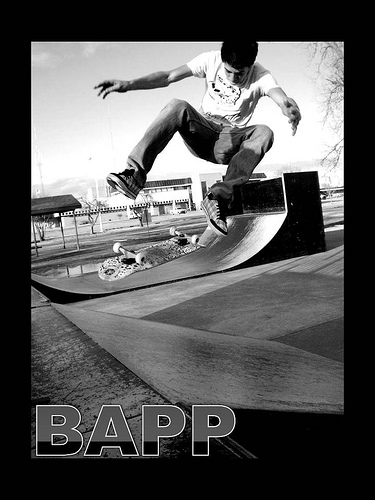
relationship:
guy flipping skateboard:
[92, 40, 301, 237] [97, 224, 201, 283]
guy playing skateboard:
[92, 40, 301, 237] [97, 224, 201, 283]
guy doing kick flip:
[92, 40, 301, 237] [93, 39, 301, 283]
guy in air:
[92, 40, 301, 237] [30, 42, 342, 312]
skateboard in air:
[97, 224, 201, 283] [30, 42, 342, 312]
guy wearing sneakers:
[92, 40, 301, 237] [107, 168, 229, 236]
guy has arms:
[92, 40, 301, 237] [93, 50, 302, 137]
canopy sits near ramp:
[30, 194, 83, 216] [31, 211, 286, 303]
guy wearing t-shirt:
[92, 40, 301, 237] [185, 49, 281, 127]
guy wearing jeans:
[92, 40, 301, 237] [127, 99, 274, 200]